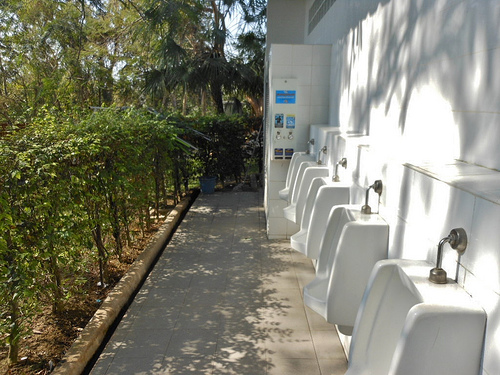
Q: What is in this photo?
A: Urinals.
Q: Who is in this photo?
A: No one.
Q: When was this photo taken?
A: During the day.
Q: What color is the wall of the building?
A: White.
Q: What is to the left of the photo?
A: Trees.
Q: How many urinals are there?
A: 5.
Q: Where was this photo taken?
A: Outside the building.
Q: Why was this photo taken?
A: To show the urinals.